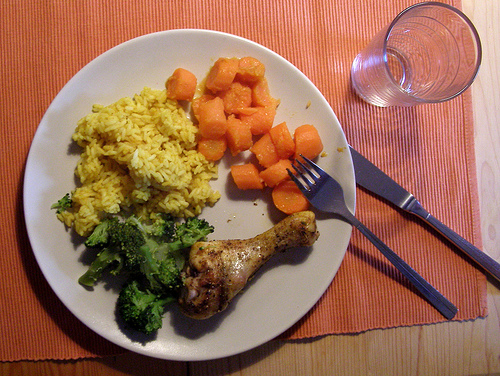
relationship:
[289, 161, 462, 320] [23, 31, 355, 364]
fork resting on plate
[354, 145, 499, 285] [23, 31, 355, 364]
knife laying beside plate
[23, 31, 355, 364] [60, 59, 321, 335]
plate holding meal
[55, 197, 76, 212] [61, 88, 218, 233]
broccoli under rice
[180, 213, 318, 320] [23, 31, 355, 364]
chicken leg on plate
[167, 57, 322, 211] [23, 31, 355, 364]
carrots on plate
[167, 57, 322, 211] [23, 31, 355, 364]
carrots on a plate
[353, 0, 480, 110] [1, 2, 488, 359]
glass on placemat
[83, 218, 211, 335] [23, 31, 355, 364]
broccoli on plate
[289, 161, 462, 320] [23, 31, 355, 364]
fork on plate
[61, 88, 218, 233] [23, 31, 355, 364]
rice on plate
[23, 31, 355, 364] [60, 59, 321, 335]
plate with complete meal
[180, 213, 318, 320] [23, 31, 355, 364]
chicken leg on a plate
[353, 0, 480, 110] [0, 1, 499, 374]
glass on a table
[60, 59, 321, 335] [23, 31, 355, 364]
meal on plate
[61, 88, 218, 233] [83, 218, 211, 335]
rice with broccoli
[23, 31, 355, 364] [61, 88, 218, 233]
plate with rice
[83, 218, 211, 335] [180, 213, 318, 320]
broccoli and chicken leg